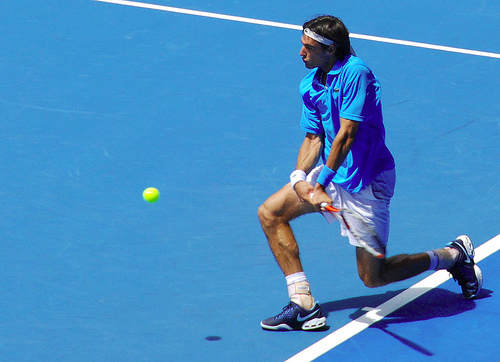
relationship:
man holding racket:
[258, 12, 485, 333] [317, 199, 387, 259]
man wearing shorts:
[258, 12, 485, 333] [306, 163, 391, 259]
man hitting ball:
[258, 12, 485, 333] [143, 187, 158, 202]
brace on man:
[287, 282, 315, 305] [258, 4, 498, 324]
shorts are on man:
[306, 163, 391, 259] [258, 12, 485, 333]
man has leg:
[258, 12, 485, 333] [349, 187, 484, 307]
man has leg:
[258, 12, 485, 333] [254, 183, 333, 328]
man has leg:
[258, 12, 485, 333] [358, 250, 430, 285]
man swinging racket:
[258, 12, 485, 333] [317, 196, 389, 268]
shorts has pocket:
[306, 163, 395, 263] [363, 182, 397, 204]